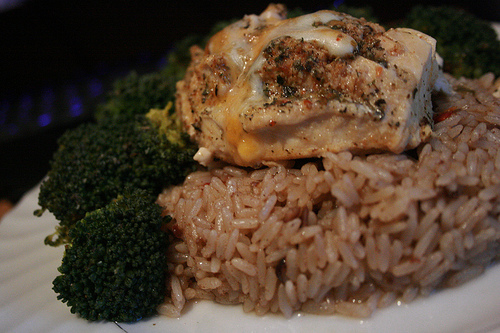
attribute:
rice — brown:
[156, 70, 499, 318]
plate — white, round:
[1, 170, 499, 331]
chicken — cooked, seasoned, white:
[173, 2, 453, 168]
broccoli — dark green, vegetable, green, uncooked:
[34, 3, 500, 324]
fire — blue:
[0, 53, 166, 146]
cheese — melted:
[196, 2, 360, 164]